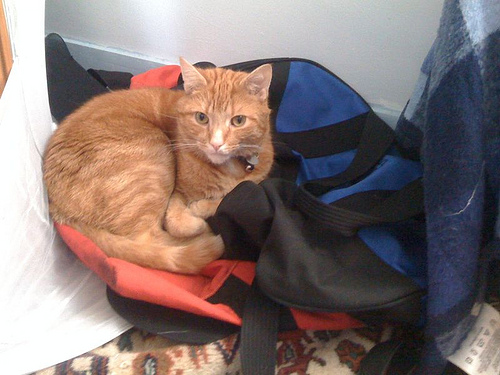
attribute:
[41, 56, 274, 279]
cat — orange, laying down, laying, sitting, resting, lying, small, black, yellow, furry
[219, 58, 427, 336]
bag — blue, black, red, lying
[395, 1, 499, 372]
blanket — blue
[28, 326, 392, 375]
rug — wool, tan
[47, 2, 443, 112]
wall — white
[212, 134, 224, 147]
nose — pink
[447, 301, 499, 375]
tag — white